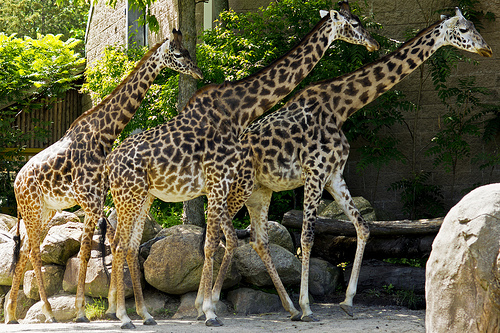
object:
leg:
[285, 184, 322, 323]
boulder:
[426, 182, 499, 333]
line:
[7, 6, 491, 326]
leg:
[16, 195, 59, 326]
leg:
[69, 196, 103, 324]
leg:
[106, 193, 136, 332]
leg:
[201, 192, 223, 331]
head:
[434, 7, 494, 59]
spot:
[223, 96, 240, 110]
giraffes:
[13, 7, 495, 329]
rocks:
[1, 203, 342, 333]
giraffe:
[99, 10, 383, 330]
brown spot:
[352, 75, 372, 87]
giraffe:
[221, 9, 481, 306]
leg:
[245, 185, 304, 320]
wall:
[228, 1, 499, 218]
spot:
[395, 58, 420, 70]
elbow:
[362, 8, 491, 108]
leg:
[68, 215, 101, 324]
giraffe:
[7, 27, 207, 318]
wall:
[343, 56, 499, 197]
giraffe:
[102, 0, 381, 331]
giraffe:
[143, 6, 493, 327]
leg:
[327, 180, 369, 317]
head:
[163, 27, 203, 80]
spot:
[303, 111, 315, 125]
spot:
[270, 134, 286, 152]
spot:
[329, 81, 350, 94]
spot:
[311, 90, 340, 103]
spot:
[259, 122, 290, 143]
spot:
[323, 90, 341, 110]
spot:
[270, 122, 290, 143]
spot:
[340, 88, 371, 106]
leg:
[248, 197, 301, 325]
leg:
[106, 199, 141, 329]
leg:
[208, 205, 235, 313]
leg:
[294, 177, 325, 327]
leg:
[203, 178, 222, 329]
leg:
[111, 198, 139, 330]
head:
[430, 6, 494, 62]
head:
[307, 6, 382, 60]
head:
[149, 25, 209, 82]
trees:
[193, 6, 428, 201]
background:
[0, 0, 500, 178]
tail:
[94, 154, 110, 284]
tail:
[8, 199, 25, 279]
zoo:
[0, 0, 500, 333]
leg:
[298, 175, 327, 324]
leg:
[244, 196, 300, 323]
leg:
[107, 200, 137, 327]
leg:
[126, 210, 157, 326]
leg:
[327, 178, 374, 318]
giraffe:
[193, 5, 493, 325]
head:
[310, 4, 382, 53]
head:
[145, 27, 207, 85]